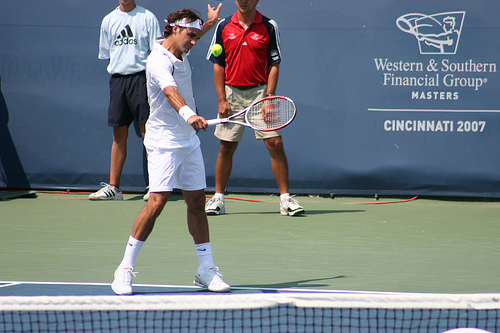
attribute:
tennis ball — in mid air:
[209, 40, 224, 59]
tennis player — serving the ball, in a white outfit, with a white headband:
[107, 5, 233, 298]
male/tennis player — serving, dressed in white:
[108, 1, 238, 296]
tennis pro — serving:
[109, 0, 233, 303]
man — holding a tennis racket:
[105, 2, 302, 299]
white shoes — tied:
[110, 262, 230, 298]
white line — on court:
[10, 272, 94, 290]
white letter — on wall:
[380, 70, 392, 87]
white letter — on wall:
[381, 117, 391, 132]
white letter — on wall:
[439, 55, 451, 74]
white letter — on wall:
[372, 54, 389, 74]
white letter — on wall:
[446, 116, 456, 135]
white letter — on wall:
[451, 88, 461, 102]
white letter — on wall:
[432, 67, 444, 91]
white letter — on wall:
[440, 55, 450, 76]